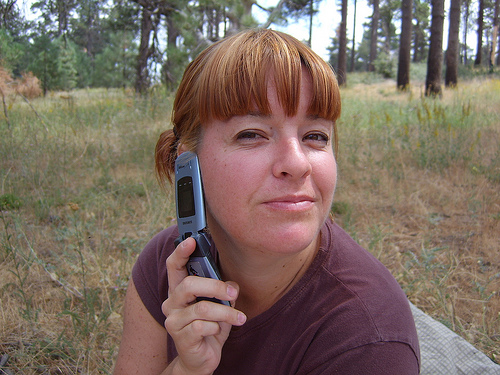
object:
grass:
[0, 76, 499, 375]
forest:
[0, 0, 500, 104]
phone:
[173, 150, 232, 307]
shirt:
[129, 210, 423, 375]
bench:
[404, 296, 500, 375]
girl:
[118, 26, 413, 374]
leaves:
[0, 0, 199, 93]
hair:
[154, 25, 343, 186]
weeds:
[0, 65, 499, 375]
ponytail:
[153, 128, 181, 195]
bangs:
[196, 27, 342, 120]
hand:
[159, 236, 246, 375]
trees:
[327, 0, 412, 92]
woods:
[0, 0, 499, 98]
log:
[408, 300, 497, 374]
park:
[1, 0, 500, 375]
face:
[200, 61, 338, 254]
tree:
[0, 0, 168, 92]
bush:
[1, 63, 44, 104]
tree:
[424, 0, 446, 104]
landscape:
[1, 0, 500, 375]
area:
[1, 0, 500, 375]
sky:
[0, 0, 500, 77]